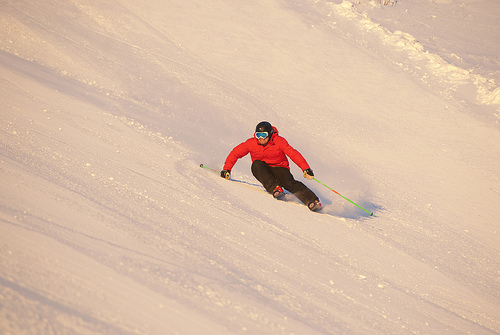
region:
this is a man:
[220, 90, 330, 230]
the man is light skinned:
[258, 138, 270, 142]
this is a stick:
[311, 175, 362, 200]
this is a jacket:
[273, 137, 297, 157]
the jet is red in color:
[266, 140, 285, 162]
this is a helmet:
[256, 118, 277, 130]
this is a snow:
[95, 51, 195, 212]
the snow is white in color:
[88, 55, 130, 124]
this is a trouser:
[269, 160, 294, 189]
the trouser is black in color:
[253, 159, 271, 179]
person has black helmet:
[245, 123, 267, 144]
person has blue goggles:
[253, 121, 273, 144]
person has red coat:
[221, 132, 318, 185]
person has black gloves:
[206, 155, 313, 184]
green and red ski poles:
[218, 162, 370, 226]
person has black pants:
[243, 171, 345, 202]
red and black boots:
[258, 175, 323, 217]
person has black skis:
[266, 189, 356, 226]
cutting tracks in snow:
[132, 25, 310, 205]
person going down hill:
[167, 31, 345, 231]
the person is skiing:
[193, 121, 375, 221]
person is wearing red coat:
[217, 127, 312, 169]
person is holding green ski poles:
[197, 160, 376, 216]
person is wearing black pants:
[248, 160, 321, 210]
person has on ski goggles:
[253, 131, 269, 139]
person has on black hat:
[255, 121, 271, 135]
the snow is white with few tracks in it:
[1, 0, 499, 334]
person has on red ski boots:
[271, 185, 323, 212]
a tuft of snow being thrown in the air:
[319, 170, 370, 219]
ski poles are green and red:
[197, 157, 374, 217]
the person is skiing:
[179, 62, 359, 270]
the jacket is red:
[207, 120, 312, 181]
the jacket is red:
[225, 132, 298, 168]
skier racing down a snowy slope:
[156, 71, 381, 237]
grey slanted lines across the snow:
[26, 155, 216, 310]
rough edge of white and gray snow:
[330, 6, 495, 111]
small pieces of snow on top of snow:
[25, 35, 165, 246]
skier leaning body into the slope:
[191, 112, 371, 217]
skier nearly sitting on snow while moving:
[215, 116, 320, 212]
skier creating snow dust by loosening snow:
[177, 80, 369, 217]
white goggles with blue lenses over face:
[216, 116, 321, 216]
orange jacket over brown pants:
[215, 120, 320, 210]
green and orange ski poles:
[300, 165, 371, 215]